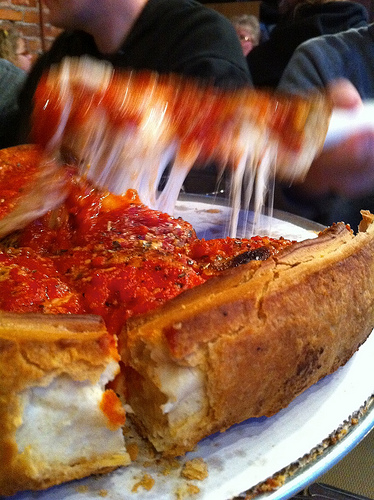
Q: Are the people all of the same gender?
A: No, they are both male and female.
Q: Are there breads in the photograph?
A: Yes, there is a bread.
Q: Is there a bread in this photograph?
A: Yes, there is a bread.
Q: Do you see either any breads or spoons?
A: Yes, there is a bread.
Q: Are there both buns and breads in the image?
A: No, there is a bread but no buns.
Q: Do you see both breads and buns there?
A: No, there is a bread but no buns.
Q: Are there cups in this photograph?
A: No, there are no cups.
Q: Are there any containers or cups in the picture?
A: No, there are no cups or containers.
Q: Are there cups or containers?
A: No, there are no cups or containers.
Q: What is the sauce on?
A: The sauce is on the pizza.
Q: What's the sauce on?
A: The sauce is on the pizza.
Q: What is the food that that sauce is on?
A: The food is a pizza.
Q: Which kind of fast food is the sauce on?
A: The sauce is on the pizza.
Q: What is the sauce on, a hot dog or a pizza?
A: The sauce is on a pizza.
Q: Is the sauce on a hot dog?
A: No, the sauce is on the pizza.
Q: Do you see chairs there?
A: No, there are no chairs.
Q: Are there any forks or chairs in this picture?
A: No, there are no chairs or forks.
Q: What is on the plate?
A: The crumbs are on the plate.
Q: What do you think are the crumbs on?
A: The crumbs are on the plate.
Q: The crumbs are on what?
A: The crumbs are on the plate.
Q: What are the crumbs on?
A: The crumbs are on the plate.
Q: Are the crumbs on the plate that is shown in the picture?
A: Yes, the crumbs are on the plate.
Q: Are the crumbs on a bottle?
A: No, the crumbs are on the plate.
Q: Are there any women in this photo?
A: Yes, there is a woman.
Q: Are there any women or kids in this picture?
A: Yes, there is a woman.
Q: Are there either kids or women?
A: Yes, there is a woman.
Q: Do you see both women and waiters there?
A: No, there is a woman but no waiters.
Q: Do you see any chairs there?
A: No, there are no chairs.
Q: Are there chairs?
A: No, there are no chairs.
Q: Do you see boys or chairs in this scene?
A: No, there are no chairs or boys.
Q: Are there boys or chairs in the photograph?
A: No, there are no chairs or boys.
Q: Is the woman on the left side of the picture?
A: Yes, the woman is on the left of the image.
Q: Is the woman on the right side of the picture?
A: No, the woman is on the left of the image.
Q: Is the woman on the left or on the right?
A: The woman is on the left of the image.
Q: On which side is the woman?
A: The woman is on the left of the image.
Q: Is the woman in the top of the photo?
A: Yes, the woman is in the top of the image.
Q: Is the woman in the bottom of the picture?
A: No, the woman is in the top of the image.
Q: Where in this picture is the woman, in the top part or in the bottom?
A: The woman is in the top of the image.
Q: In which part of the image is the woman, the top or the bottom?
A: The woman is in the top of the image.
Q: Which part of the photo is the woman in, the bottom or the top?
A: The woman is in the top of the image.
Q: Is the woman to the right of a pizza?
A: No, the woman is to the left of a pizza.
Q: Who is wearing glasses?
A: The woman is wearing glasses.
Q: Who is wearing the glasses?
A: The woman is wearing glasses.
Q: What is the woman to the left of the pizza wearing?
A: The woman is wearing glasses.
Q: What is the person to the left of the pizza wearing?
A: The woman is wearing glasses.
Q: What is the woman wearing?
A: The woman is wearing glasses.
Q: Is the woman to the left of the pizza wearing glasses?
A: Yes, the woman is wearing glasses.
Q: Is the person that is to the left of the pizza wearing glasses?
A: Yes, the woman is wearing glasses.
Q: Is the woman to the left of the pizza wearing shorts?
A: No, the woman is wearing glasses.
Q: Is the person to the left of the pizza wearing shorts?
A: No, the woman is wearing glasses.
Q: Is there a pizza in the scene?
A: Yes, there is a pizza.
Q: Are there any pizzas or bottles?
A: Yes, there is a pizza.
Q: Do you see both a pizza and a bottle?
A: No, there is a pizza but no bottles.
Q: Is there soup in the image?
A: No, there is no soup.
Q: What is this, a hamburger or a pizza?
A: This is a pizza.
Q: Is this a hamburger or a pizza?
A: This is a pizza.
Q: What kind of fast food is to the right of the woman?
A: The food is a pizza.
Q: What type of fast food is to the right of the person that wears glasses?
A: The food is a pizza.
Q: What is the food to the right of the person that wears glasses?
A: The food is a pizza.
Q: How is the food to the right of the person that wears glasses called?
A: The food is a pizza.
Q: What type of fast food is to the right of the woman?
A: The food is a pizza.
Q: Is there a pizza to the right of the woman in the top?
A: Yes, there is a pizza to the right of the woman.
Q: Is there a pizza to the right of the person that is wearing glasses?
A: Yes, there is a pizza to the right of the woman.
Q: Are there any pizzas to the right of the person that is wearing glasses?
A: Yes, there is a pizza to the right of the woman.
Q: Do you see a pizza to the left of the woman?
A: No, the pizza is to the right of the woman.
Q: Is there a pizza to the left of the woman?
A: No, the pizza is to the right of the woman.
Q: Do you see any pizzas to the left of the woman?
A: No, the pizza is to the right of the woman.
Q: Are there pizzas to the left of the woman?
A: No, the pizza is to the right of the woman.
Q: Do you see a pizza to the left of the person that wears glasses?
A: No, the pizza is to the right of the woman.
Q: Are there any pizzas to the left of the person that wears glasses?
A: No, the pizza is to the right of the woman.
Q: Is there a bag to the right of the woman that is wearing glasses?
A: No, there is a pizza to the right of the woman.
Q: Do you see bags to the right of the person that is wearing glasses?
A: No, there is a pizza to the right of the woman.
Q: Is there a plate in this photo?
A: Yes, there is a plate.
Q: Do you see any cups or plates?
A: Yes, there is a plate.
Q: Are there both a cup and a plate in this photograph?
A: No, there is a plate but no cups.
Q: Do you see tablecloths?
A: No, there are no tablecloths.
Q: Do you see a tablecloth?
A: No, there are no tablecloths.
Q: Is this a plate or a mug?
A: This is a plate.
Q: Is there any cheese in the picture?
A: Yes, there is cheese.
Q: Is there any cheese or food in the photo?
A: Yes, there is cheese.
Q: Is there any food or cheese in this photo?
A: Yes, there is cheese.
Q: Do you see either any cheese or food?
A: Yes, there is cheese.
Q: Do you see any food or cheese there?
A: Yes, there is cheese.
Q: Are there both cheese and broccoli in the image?
A: No, there is cheese but no broccoli.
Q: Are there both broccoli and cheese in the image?
A: No, there is cheese but no broccoli.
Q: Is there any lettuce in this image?
A: No, there is no lettuce.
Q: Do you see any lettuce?
A: No, there is no lettuce.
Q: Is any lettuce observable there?
A: No, there is no lettuce.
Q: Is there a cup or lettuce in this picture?
A: No, there are no lettuce or cups.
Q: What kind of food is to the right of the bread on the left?
A: The food is cheese.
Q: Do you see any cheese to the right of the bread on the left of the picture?
A: Yes, there is cheese to the right of the bread.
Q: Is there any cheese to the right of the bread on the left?
A: Yes, there is cheese to the right of the bread.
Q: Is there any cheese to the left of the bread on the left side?
A: No, the cheese is to the right of the bread.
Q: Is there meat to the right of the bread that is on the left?
A: No, there is cheese to the right of the bread.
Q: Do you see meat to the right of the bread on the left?
A: No, there is cheese to the right of the bread.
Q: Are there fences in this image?
A: No, there are no fences.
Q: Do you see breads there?
A: Yes, there is a bread.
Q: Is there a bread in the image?
A: Yes, there is a bread.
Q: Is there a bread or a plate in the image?
A: Yes, there is a bread.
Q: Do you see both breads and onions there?
A: No, there is a bread but no onions.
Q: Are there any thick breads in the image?
A: Yes, there is a thick bread.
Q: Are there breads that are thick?
A: Yes, there is a bread that is thick.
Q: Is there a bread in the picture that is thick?
A: Yes, there is a bread that is thick.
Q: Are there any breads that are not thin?
A: Yes, there is a thick bread.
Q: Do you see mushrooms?
A: No, there are no mushrooms.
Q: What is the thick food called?
A: The food is a bread.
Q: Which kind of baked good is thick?
A: The baked good is a bread.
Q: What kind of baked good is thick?
A: The baked good is a bread.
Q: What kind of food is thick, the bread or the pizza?
A: The bread is thick.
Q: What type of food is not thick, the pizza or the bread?
A: The pizza is not thick.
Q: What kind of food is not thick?
A: The food is a pizza.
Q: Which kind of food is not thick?
A: The food is a pizza.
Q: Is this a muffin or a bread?
A: This is a bread.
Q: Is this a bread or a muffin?
A: This is a bread.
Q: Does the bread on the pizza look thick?
A: Yes, the bread is thick.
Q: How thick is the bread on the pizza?
A: The bread is thick.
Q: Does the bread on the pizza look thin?
A: No, the bread is thick.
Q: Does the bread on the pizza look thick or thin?
A: The bread is thick.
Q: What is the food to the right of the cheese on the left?
A: The food is a bread.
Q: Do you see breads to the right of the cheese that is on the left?
A: Yes, there is a bread to the right of the cheese.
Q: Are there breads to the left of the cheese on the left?
A: No, the bread is to the right of the cheese.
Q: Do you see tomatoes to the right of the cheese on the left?
A: No, there is a bread to the right of the cheese.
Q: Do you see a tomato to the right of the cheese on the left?
A: No, there is a bread to the right of the cheese.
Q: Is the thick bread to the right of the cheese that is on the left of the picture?
A: Yes, the bread is to the right of the cheese.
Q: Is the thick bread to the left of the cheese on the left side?
A: No, the bread is to the right of the cheese.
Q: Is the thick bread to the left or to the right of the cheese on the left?
A: The bread is to the right of the cheese.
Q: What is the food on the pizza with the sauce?
A: The food is a bread.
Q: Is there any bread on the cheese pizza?
A: Yes, there is a bread on the pizza.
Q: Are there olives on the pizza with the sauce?
A: No, there is a bread on the pizza.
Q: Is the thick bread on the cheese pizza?
A: Yes, the bread is on the pizza.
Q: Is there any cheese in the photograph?
A: Yes, there is cheese.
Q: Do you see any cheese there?
A: Yes, there is cheese.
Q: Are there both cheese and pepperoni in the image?
A: No, there is cheese but no pepperoni.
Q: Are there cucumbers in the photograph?
A: No, there are no cucumbers.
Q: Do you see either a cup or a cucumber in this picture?
A: No, there are no cucumbers or cups.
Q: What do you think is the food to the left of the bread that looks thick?
A: The food is cheese.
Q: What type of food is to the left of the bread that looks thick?
A: The food is cheese.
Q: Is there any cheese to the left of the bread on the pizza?
A: Yes, there is cheese to the left of the bread.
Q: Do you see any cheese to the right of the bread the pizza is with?
A: No, the cheese is to the left of the bread.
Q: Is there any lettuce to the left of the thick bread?
A: No, there is cheese to the left of the bread.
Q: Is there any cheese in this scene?
A: Yes, there is cheese.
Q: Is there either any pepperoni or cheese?
A: Yes, there is cheese.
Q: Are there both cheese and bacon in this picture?
A: No, there is cheese but no bacon.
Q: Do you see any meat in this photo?
A: No, there is no meat.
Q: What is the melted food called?
A: The food is cheese.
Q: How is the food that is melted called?
A: The food is cheese.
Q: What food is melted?
A: The food is cheese.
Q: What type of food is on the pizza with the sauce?
A: The food is cheese.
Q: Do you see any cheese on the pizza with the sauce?
A: Yes, there is cheese on the pizza.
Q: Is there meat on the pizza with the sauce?
A: No, there is cheese on the pizza.